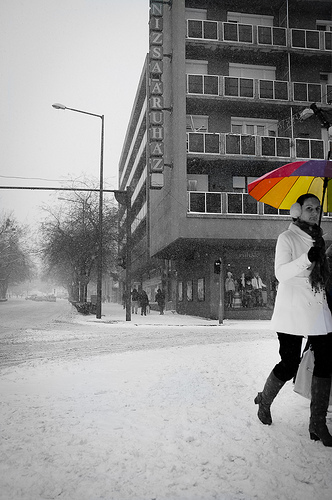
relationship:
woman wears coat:
[250, 192, 331, 450] [266, 220, 331, 340]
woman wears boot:
[250, 192, 331, 450] [251, 369, 287, 427]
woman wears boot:
[250, 192, 331, 450] [306, 373, 331, 448]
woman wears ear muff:
[250, 192, 331, 450] [288, 201, 304, 222]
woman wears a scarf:
[250, 192, 331, 450] [292, 216, 330, 296]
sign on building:
[142, 3, 168, 193] [114, 1, 331, 326]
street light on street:
[49, 99, 105, 322] [2, 291, 331, 499]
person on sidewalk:
[154, 287, 168, 316] [68, 290, 273, 330]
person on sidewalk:
[138, 288, 152, 317] [68, 290, 273, 330]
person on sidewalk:
[130, 284, 139, 318] [68, 290, 273, 330]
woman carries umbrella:
[250, 192, 331, 450] [246, 156, 330, 268]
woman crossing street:
[250, 192, 331, 450] [2, 291, 331, 499]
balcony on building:
[186, 53, 289, 106] [114, 1, 331, 326]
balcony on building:
[186, 1, 287, 52] [114, 1, 331, 326]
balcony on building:
[185, 101, 291, 161] [114, 1, 331, 326]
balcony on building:
[186, 158, 292, 218] [114, 1, 331, 326]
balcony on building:
[291, 8, 331, 50] [114, 1, 331, 326]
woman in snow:
[250, 192, 331, 450] [2, 284, 327, 499]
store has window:
[168, 238, 282, 321] [221, 260, 279, 314]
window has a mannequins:
[221, 260, 279, 314] [225, 265, 270, 312]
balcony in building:
[186, 1, 287, 52] [114, 1, 331, 326]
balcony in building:
[186, 53, 289, 106] [114, 1, 331, 326]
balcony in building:
[185, 101, 291, 161] [114, 1, 331, 326]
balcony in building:
[291, 8, 331, 50] [114, 1, 331, 326]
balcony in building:
[186, 158, 292, 218] [114, 1, 331, 326]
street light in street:
[49, 99, 105, 322] [2, 291, 331, 499]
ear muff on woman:
[288, 201, 304, 222] [250, 192, 331, 450]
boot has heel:
[251, 369, 287, 427] [252, 393, 263, 407]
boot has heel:
[306, 373, 331, 448] [307, 431, 321, 443]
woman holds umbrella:
[250, 192, 331, 450] [246, 156, 330, 268]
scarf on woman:
[292, 216, 330, 296] [250, 192, 331, 450]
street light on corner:
[49, 99, 105, 322] [53, 270, 227, 332]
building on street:
[114, 1, 331, 326] [2, 291, 331, 499]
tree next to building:
[38, 186, 127, 316] [114, 1, 331, 326]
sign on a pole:
[212, 256, 224, 277] [215, 253, 225, 328]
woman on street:
[250, 192, 331, 450] [2, 291, 331, 499]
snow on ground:
[2, 284, 327, 499] [2, 296, 331, 499]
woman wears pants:
[250, 192, 331, 450] [270, 331, 331, 382]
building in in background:
[114, 1, 331, 326] [0, 0, 332, 326]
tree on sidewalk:
[38, 186, 127, 316] [68, 290, 273, 330]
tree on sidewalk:
[43, 217, 81, 305] [68, 290, 273, 330]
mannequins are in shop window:
[225, 265, 270, 312] [221, 260, 279, 314]